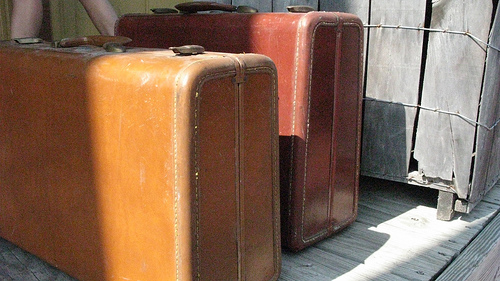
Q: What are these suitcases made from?
A: Leather.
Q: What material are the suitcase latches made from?
A: Metal.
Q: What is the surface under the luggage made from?
A: Wood.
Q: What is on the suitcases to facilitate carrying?
A: Handles.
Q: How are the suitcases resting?
A: Standing upright.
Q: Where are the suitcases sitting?
A: On the ground.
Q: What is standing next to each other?
A: Two suitcases.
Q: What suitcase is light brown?
A: The left one.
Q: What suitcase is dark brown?
A: The right one.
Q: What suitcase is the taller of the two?
A: The right one.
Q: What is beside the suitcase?
A: A wooden box.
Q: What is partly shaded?
A: The suitcases.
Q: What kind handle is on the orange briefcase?
A: A silver handle.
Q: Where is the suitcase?
A: On the ramp.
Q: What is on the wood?
A: Two suitcases.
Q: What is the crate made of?
A: Wood and wire.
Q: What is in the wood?
A: Screws.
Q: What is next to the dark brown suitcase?
A: Tan suitcase.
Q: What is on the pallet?
A: Two suitcases.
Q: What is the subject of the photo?
A: Suitcases.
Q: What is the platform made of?
A: Wood.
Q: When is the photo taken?
A: Daytime.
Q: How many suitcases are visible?
A: Two.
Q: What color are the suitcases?
A: Brown.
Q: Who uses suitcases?
A: Travelers.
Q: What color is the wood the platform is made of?
A: Grey.